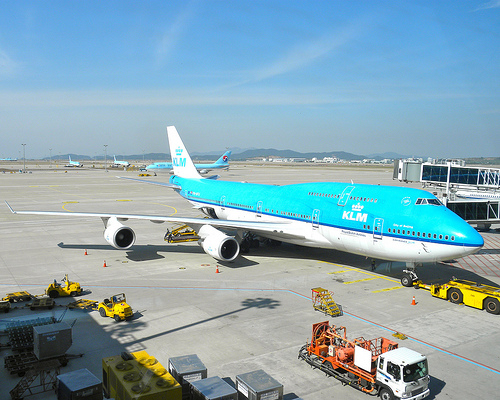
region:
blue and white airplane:
[13, 117, 482, 278]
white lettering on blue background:
[341, 205, 368, 222]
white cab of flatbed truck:
[305, 321, 433, 399]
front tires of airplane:
[395, 274, 413, 287]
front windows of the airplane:
[413, 197, 438, 208]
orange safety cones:
[76, 247, 421, 310]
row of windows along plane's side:
[263, 202, 461, 248]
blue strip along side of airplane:
[180, 191, 482, 246]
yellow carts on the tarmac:
[46, 273, 139, 320]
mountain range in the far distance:
[38, 144, 368, 166]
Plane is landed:
[6, 120, 488, 287]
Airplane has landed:
[5, 120, 490, 289]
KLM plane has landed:
[7, 120, 484, 287]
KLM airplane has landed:
[9, 120, 485, 287]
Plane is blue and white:
[4, 121, 483, 289]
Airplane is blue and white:
[1, 120, 483, 291]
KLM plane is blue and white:
[0, 124, 487, 291]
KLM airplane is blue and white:
[5, 121, 488, 294]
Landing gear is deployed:
[397, 260, 424, 289]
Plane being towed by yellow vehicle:
[401, 268, 498, 318]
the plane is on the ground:
[16, 126, 481, 266]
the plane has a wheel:
[401, 268, 417, 282]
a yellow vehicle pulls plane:
[409, 270, 499, 313]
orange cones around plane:
[82, 246, 417, 303]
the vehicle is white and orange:
[306, 320, 432, 397]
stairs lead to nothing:
[313, 285, 340, 321]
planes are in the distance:
[66, 153, 236, 173]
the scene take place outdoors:
[0, 0, 499, 398]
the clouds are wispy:
[0, 0, 498, 159]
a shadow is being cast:
[0, 288, 280, 396]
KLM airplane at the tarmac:
[25, 105, 477, 277]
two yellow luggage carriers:
[40, 265, 134, 320]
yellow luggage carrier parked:
[440, 268, 495, 328]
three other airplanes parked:
[5, 152, 133, 170]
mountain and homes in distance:
[252, 143, 387, 173]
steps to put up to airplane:
[304, 278, 343, 316]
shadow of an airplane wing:
[65, 243, 246, 284]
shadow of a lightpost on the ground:
[131, 293, 298, 336]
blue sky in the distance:
[201, 85, 395, 138]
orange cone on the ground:
[402, 295, 419, 309]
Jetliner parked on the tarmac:
[1, 116, 488, 272]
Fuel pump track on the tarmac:
[297, 308, 437, 398]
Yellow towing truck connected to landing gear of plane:
[397, 264, 499, 317]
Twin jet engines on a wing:
[98, 210, 243, 265]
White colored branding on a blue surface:
[340, 200, 377, 223]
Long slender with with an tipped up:
[2, 190, 302, 240]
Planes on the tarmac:
[62, 151, 250, 173]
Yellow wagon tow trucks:
[0, 273, 140, 323]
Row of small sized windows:
[361, 221, 460, 244]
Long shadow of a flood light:
[113, 293, 284, 345]